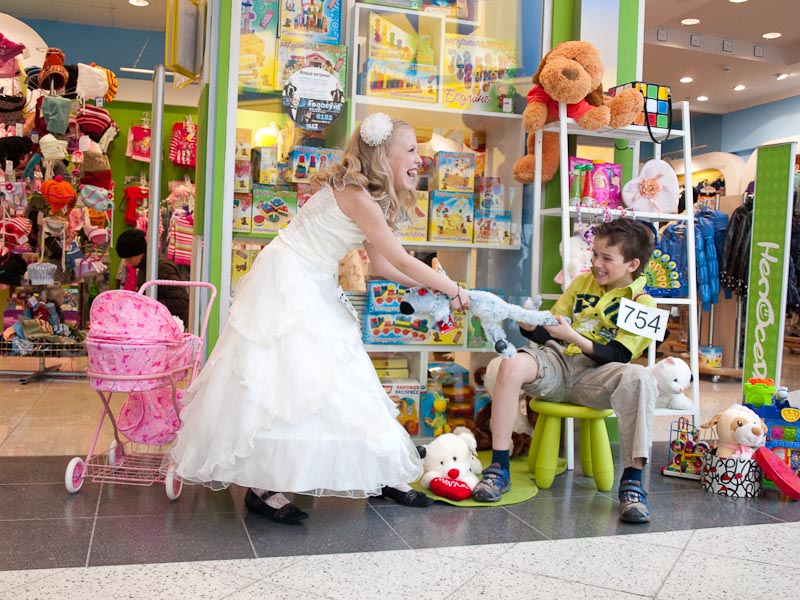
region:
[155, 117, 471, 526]
the girl is wearing a white dress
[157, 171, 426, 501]
the dress is white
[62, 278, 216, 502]
the doll stroller is pink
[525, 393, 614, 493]
the stool is green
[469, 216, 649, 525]
the boy sitting on the stool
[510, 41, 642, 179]
the stuffed toy dog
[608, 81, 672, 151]
the large rubiks cube has straps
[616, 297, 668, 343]
the white paper with the black numbers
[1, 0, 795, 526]
the children in front of the store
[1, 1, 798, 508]
the toys in and outside of the store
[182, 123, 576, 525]
girl is pulling on stuffed toy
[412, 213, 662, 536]
boy is pulling on stuffed toy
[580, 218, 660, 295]
boy has brown hair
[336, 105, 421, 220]
girl has white barrette in her hair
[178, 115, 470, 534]
girl is wearing a white dress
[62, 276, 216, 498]
doll stroller is pink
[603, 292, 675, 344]
boy has a tag numbered 754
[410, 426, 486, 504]
teddy bear is white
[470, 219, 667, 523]
boy sits on green stool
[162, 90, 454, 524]
Girl wearing white dress.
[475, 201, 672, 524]
Boy sitting down in a chair.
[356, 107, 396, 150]
White lace bow in girl's hair.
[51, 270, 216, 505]
Pink toy stroller with white and pink wheels.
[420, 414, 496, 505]
White stuffed animal with red nose.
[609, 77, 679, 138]
Large rubik's cube with black strap.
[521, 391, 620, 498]
Green stool with four legs.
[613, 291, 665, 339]
White card with the number '754' on it.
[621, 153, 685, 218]
White heart shaped box on shelf.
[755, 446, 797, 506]
Round red top belonging to a box.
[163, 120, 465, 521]
the girl is young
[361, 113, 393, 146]
white bow in hair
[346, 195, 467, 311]
arm of a girl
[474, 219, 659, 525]
boy is sitting down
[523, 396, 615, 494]
the stool is yellow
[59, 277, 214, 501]
white and pink stroller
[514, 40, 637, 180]
the dog is stuffed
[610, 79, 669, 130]
a large rubicks cube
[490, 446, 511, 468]
the sock is blue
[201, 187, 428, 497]
kids bright white gown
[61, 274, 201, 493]
pink toy baby carriage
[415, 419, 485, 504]
white and red stuffed bear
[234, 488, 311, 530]
girls black dress shoe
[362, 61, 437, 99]
toy on white shelf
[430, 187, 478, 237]
toy on white shelf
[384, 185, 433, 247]
toy on white shelf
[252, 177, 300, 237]
toy on white shelf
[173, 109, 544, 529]
Young girl in white dress holding a stuffed animal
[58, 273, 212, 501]
Pink baby carriage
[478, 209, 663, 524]
Boy in green shirt sitting on chair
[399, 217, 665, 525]
Boy in green shirt sitting on chair pulling stuffed animal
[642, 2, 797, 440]
Clothing store inside mall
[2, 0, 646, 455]
Baby clothes and toys store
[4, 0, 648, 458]
Baby clothes and toys store in mall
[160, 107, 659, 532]
Young girl and boy tugging a stuffed animal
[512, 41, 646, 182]
Big tan stuffed bear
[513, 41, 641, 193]
Big tan stuffed bear sitting up high on shelf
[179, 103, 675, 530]
kids playing tug o war with a stuffed animal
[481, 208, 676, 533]
boy sitting on a stool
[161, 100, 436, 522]
girl wearing a pretty white dress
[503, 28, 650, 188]
stuffed dog on a shelf